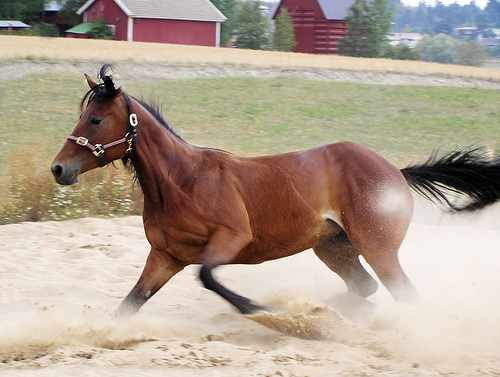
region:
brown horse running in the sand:
[41, 54, 498, 328]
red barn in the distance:
[273, 0, 385, 59]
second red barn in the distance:
[75, 0, 243, 68]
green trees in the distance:
[348, 1, 397, 73]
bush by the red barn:
[15, 17, 66, 42]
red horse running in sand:
[41, 63, 483, 331]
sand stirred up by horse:
[247, 291, 366, 347]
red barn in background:
[274, 2, 390, 53]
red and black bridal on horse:
[64, 87, 136, 170]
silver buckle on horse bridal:
[127, 109, 139, 130]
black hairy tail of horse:
[394, 146, 499, 212]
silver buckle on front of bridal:
[75, 134, 89, 146]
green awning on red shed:
[65, 19, 102, 34]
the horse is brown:
[18, 52, 437, 342]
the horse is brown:
[32, 75, 442, 348]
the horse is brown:
[41, 79, 403, 354]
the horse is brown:
[35, 62, 427, 354]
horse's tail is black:
[392, 131, 494, 246]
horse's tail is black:
[388, 132, 497, 239]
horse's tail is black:
[384, 140, 489, 224]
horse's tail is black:
[385, 128, 492, 248]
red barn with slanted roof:
[77, 0, 226, 42]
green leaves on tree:
[341, 2, 396, 58]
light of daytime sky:
[401, 0, 488, 8]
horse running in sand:
[1, 60, 494, 374]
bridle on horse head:
[52, 87, 137, 183]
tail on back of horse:
[401, 150, 497, 213]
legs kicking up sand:
[11, 260, 426, 350]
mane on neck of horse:
[128, 90, 197, 145]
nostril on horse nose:
[51, 161, 74, 184]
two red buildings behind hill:
[68, 0, 370, 55]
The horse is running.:
[51, 64, 498, 348]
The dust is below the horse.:
[1, 264, 492, 352]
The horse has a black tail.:
[398, 144, 498, 216]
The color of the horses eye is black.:
[88, 114, 105, 128]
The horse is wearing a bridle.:
[48, 62, 160, 184]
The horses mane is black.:
[47, 62, 194, 198]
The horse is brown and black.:
[49, 59, 498, 340]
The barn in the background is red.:
[67, 0, 227, 47]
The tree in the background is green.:
[337, 1, 395, 58]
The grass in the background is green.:
[253, 97, 340, 135]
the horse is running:
[0, 13, 465, 308]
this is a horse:
[72, 86, 411, 256]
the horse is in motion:
[83, 92, 419, 308]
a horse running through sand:
[42, 60, 496, 347]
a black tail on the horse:
[393, 141, 498, 238]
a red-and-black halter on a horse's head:
[60, 83, 141, 170]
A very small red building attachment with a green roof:
[60, 16, 115, 40]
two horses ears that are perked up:
[80, 68, 119, 104]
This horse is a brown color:
[44, 73, 472, 354]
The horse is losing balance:
[107, 229, 462, 353]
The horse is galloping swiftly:
[28, 76, 492, 326]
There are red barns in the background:
[58, 5, 498, 92]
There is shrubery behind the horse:
[25, 65, 486, 205]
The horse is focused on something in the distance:
[33, 72, 194, 237]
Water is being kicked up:
[206, 288, 452, 373]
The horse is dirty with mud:
[114, 151, 498, 358]